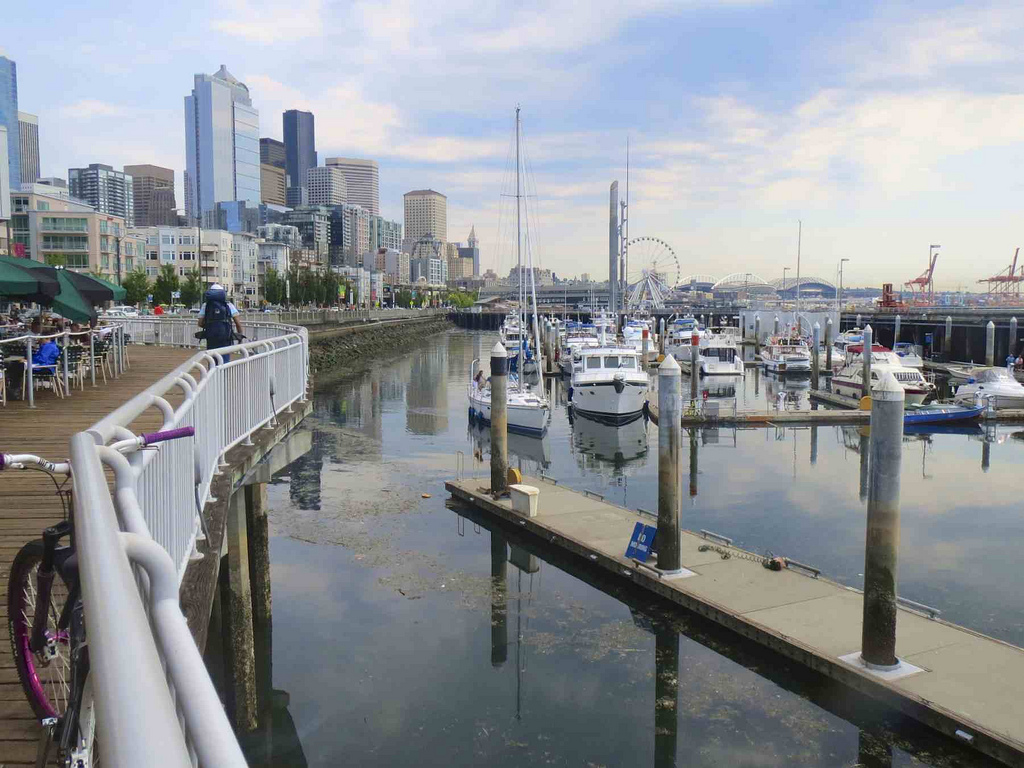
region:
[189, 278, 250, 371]
a man carrying a big backpack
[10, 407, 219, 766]
a bicycle leaning on steel sidings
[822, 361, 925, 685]
a big concrete pole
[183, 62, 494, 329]
skyline of lots of buildings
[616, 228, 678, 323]
a white ferris wheel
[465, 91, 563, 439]
a tall mast of a yacht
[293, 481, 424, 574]
muck and dirt floating on the water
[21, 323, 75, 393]
a person wearing a blue shirt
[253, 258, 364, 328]
series of trees on the side of a street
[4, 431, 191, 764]
The white bicycle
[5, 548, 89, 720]
The front wheel of the bike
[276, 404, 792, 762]
The green sea moss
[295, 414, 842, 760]
A area of green sea moss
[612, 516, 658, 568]
A blue and white sign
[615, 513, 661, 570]
The blue and white sign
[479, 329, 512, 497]
The wooden post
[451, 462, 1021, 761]
A wooden dock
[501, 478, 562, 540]
A white container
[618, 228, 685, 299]
ferris wheel across the marina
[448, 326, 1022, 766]
unused docking area for boats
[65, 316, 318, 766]
a white railing on the deck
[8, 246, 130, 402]
people dining outside under green umbrellas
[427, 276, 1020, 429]
marina filled with docked boats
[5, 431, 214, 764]
bicycle tied to a white railing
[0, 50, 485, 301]
highrise building of a large city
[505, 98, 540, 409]
mast of a docked sailboat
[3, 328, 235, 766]
wooden deck along the water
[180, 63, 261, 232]
high rise made of highly reflective glass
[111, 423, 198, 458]
purple bike handle through railing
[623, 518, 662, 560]
blue sign on dock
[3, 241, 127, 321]
green and black umbrellas over tables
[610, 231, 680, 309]
large ferris wheel behind marina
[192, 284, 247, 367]
person with large backpack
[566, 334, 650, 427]
boat hooked up to dock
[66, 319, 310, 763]
white metal railing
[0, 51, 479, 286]
tall buildings near the water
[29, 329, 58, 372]
person in blue shirt under umbrellas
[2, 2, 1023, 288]
partly cloudy sky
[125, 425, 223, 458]
handle bar is purple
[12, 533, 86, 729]
bike has wheel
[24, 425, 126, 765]
bicycle tied to the rail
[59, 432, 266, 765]
railing is white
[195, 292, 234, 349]
man is wearing backpack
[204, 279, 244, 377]
backpack is blue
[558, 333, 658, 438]
boat is while and blue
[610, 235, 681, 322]
ferris wheel behind boats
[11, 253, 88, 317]
umbrellas are green in color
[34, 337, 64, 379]
shirt is blue in color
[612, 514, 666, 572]
blue and white sign on pier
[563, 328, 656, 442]
white boat in the water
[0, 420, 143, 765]
bicycle sitting by the railing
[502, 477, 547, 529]
white box sitting on pier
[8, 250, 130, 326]
green umbrellas over chairs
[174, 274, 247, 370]
man riding a bicycle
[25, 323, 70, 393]
man wearing blue shirt sitting in chair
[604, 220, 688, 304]
ferris wheel in the distance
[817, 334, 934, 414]
red and white boat in water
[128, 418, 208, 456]
purple handlebar on bicycle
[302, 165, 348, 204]
A building in a city.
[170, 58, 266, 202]
A building in a city.